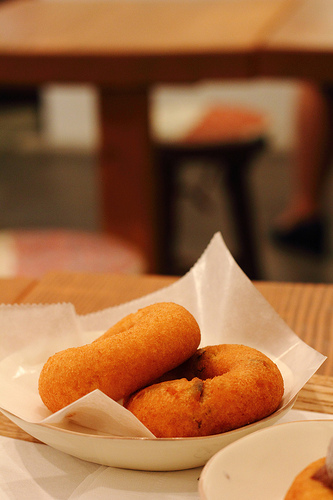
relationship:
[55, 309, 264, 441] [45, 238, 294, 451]
donuts on paper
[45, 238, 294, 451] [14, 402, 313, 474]
paper on top of plate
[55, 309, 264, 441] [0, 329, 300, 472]
donuts on plate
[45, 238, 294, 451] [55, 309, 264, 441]
paper under donuts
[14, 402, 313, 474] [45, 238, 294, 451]
bowl under paper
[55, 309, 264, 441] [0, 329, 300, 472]
donuts inside plate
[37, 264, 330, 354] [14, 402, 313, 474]
table under plate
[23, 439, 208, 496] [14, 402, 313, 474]
shadow under plate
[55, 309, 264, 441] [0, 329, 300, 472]
donuts in plate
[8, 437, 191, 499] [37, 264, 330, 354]
paper on table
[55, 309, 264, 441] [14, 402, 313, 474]
donuts in plate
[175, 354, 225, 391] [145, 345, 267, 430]
hole in donut